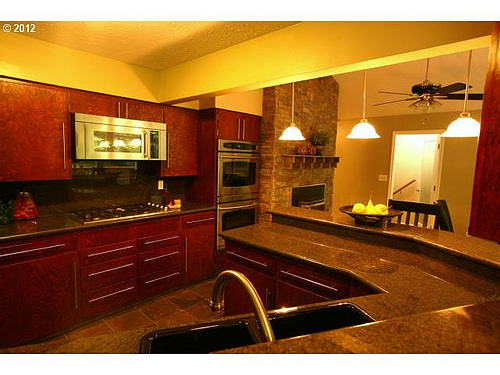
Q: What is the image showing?
A: It is showing a kitchen.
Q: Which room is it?
A: It is a kitchen.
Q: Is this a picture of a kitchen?
A: Yes, it is showing a kitchen.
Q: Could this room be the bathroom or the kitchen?
A: It is the kitchen.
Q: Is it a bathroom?
A: No, it is a kitchen.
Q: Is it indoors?
A: Yes, it is indoors.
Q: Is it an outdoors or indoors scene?
A: It is indoors.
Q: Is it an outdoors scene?
A: No, it is indoors.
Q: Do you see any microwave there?
A: Yes, there is a microwave.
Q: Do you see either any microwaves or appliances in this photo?
A: Yes, there is a microwave.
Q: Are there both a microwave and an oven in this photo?
A: Yes, there are both a microwave and an oven.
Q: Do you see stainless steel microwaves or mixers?
A: Yes, there is a stainless steel microwave.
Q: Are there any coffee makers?
A: No, there are no coffee makers.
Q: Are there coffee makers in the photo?
A: No, there are no coffee makers.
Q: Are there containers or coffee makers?
A: No, there are no coffee makers or containers.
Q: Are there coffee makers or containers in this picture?
A: No, there are no coffee makers or containers.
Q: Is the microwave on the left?
A: Yes, the microwave is on the left of the image.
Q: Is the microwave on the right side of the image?
A: No, the microwave is on the left of the image.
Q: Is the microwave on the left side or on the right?
A: The microwave is on the left of the image.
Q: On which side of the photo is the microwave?
A: The microwave is on the left of the image.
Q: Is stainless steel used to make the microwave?
A: Yes, the microwave is made of stainless steel.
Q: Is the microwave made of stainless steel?
A: Yes, the microwave is made of stainless steel.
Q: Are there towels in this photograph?
A: No, there are no towels.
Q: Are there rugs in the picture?
A: No, there are no rugs.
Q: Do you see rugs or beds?
A: No, there are no rugs or beds.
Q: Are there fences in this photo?
A: No, there are no fences.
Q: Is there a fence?
A: No, there are no fences.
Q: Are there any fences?
A: No, there are no fences.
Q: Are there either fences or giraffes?
A: No, there are no fences or giraffes.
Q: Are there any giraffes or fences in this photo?
A: No, there are no fences or giraffes.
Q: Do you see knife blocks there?
A: No, there are no knife blocks.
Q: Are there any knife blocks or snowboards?
A: No, there are no knife blocks or snowboards.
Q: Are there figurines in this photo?
A: No, there are no figurines.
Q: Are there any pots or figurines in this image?
A: No, there are no figurines or pots.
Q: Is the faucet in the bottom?
A: Yes, the faucet is in the bottom of the image.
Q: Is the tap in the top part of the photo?
A: No, the tap is in the bottom of the image.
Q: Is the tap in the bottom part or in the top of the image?
A: The tap is in the bottom of the image.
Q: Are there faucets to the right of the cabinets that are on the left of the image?
A: Yes, there is a faucet to the right of the cabinets.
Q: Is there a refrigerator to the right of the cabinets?
A: No, there is a faucet to the right of the cabinets.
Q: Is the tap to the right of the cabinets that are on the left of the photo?
A: Yes, the tap is to the right of the cabinets.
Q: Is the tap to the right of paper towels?
A: No, the tap is to the right of the cabinets.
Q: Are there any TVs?
A: No, there are no tvs.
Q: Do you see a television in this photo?
A: No, there are no televisions.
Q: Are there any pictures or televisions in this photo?
A: No, there are no televisions or pictures.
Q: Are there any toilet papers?
A: No, there are no toilet papers.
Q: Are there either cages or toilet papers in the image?
A: No, there are no toilet papers or cages.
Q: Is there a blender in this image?
A: No, there are no blenders.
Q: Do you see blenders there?
A: No, there are no blenders.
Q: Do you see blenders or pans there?
A: No, there are no blenders or pans.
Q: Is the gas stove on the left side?
A: Yes, the gas stove is on the left of the image.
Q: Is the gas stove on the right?
A: No, the gas stove is on the left of the image.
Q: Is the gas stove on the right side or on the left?
A: The gas stove is on the left of the image.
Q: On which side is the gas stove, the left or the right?
A: The gas stove is on the left of the image.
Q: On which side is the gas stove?
A: The gas stove is on the left of the image.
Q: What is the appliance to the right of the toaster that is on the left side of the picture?
A: The appliance is a gas stove.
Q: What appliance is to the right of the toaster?
A: The appliance is a gas stove.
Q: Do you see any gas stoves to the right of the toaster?
A: Yes, there is a gas stove to the right of the toaster.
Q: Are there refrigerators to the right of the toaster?
A: No, there is a gas stove to the right of the toaster.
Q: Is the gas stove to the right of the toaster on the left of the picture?
A: Yes, the gas stove is to the right of the toaster.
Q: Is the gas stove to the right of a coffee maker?
A: No, the gas stove is to the right of the toaster.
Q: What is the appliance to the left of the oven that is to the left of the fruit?
A: The appliance is a gas stove.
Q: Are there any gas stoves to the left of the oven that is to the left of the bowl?
A: Yes, there is a gas stove to the left of the oven.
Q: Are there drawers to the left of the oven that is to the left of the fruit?
A: No, there is a gas stove to the left of the oven.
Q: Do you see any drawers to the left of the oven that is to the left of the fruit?
A: No, there is a gas stove to the left of the oven.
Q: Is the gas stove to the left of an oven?
A: Yes, the gas stove is to the left of an oven.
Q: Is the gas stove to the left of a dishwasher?
A: No, the gas stove is to the left of an oven.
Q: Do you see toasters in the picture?
A: Yes, there is a toaster.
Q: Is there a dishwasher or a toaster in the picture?
A: Yes, there is a toaster.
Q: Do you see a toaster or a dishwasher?
A: Yes, there is a toaster.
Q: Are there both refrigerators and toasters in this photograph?
A: No, there is a toaster but no refrigerators.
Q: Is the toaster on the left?
A: Yes, the toaster is on the left of the image.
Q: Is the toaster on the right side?
A: No, the toaster is on the left of the image.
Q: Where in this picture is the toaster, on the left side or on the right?
A: The toaster is on the left of the image.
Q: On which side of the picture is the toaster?
A: The toaster is on the left of the image.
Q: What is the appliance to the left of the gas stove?
A: The appliance is a toaster.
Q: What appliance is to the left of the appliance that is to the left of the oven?
A: The appliance is a toaster.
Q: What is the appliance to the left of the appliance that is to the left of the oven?
A: The appliance is a toaster.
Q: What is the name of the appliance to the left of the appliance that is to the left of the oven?
A: The appliance is a toaster.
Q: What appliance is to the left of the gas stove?
A: The appliance is a toaster.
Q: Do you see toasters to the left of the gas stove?
A: Yes, there is a toaster to the left of the gas stove.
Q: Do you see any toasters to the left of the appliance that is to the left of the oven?
A: Yes, there is a toaster to the left of the gas stove.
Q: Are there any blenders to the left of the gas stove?
A: No, there is a toaster to the left of the gas stove.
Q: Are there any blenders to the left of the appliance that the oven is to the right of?
A: No, there is a toaster to the left of the gas stove.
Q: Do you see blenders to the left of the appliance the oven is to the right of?
A: No, there is a toaster to the left of the gas stove.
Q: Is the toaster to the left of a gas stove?
A: Yes, the toaster is to the left of a gas stove.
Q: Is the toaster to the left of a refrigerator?
A: No, the toaster is to the left of a gas stove.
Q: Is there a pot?
A: No, there are no pots.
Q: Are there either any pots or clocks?
A: No, there are no pots or clocks.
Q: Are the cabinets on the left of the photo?
A: Yes, the cabinets are on the left of the image.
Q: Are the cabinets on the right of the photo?
A: No, the cabinets are on the left of the image.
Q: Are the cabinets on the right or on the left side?
A: The cabinets are on the left of the image.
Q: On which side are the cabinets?
A: The cabinets are on the left of the image.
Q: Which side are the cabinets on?
A: The cabinets are on the left of the image.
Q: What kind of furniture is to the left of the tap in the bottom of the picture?
A: The pieces of furniture are cabinets.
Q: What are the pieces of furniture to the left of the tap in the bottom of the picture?
A: The pieces of furniture are cabinets.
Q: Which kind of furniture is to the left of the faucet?
A: The pieces of furniture are cabinets.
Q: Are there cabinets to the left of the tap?
A: Yes, there are cabinets to the left of the tap.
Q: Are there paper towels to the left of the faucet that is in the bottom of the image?
A: No, there are cabinets to the left of the tap.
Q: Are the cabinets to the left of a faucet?
A: Yes, the cabinets are to the left of a faucet.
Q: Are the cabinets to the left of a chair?
A: No, the cabinets are to the left of a faucet.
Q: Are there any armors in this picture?
A: No, there are no armors.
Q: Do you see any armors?
A: No, there are no armors.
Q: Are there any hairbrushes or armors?
A: No, there are no armors or hairbrushes.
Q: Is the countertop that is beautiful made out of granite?
A: Yes, the counter top is made of granite.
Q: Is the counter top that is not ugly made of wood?
A: No, the counter top is made of granite.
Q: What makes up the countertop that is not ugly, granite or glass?
A: The counter top is made of granite.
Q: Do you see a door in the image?
A: Yes, there is a door.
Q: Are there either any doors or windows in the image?
A: Yes, there is a door.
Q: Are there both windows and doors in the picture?
A: No, there is a door but no windows.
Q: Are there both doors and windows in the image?
A: No, there is a door but no windows.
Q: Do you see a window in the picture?
A: No, there are no windows.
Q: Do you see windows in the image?
A: No, there are no windows.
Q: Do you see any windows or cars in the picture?
A: No, there are no windows or cars.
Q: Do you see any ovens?
A: Yes, there is an oven.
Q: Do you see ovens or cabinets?
A: Yes, there is an oven.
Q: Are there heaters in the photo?
A: No, there are no heaters.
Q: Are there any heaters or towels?
A: No, there are no heaters or towels.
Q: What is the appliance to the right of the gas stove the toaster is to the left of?
A: The appliance is an oven.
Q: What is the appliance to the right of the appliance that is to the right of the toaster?
A: The appliance is an oven.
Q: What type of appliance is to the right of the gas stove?
A: The appliance is an oven.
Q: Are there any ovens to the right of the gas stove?
A: Yes, there is an oven to the right of the gas stove.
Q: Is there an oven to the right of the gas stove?
A: Yes, there is an oven to the right of the gas stove.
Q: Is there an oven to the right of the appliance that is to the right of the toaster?
A: Yes, there is an oven to the right of the gas stove.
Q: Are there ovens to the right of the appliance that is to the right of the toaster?
A: Yes, there is an oven to the right of the gas stove.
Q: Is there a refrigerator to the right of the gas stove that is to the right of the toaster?
A: No, there is an oven to the right of the gas stove.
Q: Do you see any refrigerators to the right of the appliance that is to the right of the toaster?
A: No, there is an oven to the right of the gas stove.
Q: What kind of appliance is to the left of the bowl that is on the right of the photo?
A: The appliance is an oven.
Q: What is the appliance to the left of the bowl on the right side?
A: The appliance is an oven.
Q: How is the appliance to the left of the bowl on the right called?
A: The appliance is an oven.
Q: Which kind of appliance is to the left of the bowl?
A: The appliance is an oven.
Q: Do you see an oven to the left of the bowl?
A: Yes, there is an oven to the left of the bowl.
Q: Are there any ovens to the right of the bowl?
A: No, the oven is to the left of the bowl.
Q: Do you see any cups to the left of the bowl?
A: No, there is an oven to the left of the bowl.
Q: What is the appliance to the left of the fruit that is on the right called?
A: The appliance is an oven.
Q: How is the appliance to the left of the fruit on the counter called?
A: The appliance is an oven.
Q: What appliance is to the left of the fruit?
A: The appliance is an oven.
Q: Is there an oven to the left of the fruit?
A: Yes, there is an oven to the left of the fruit.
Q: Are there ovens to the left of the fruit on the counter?
A: Yes, there is an oven to the left of the fruit.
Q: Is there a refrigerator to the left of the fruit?
A: No, there is an oven to the left of the fruit.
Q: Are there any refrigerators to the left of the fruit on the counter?
A: No, there is an oven to the left of the fruit.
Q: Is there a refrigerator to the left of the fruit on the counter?
A: No, there is an oven to the left of the fruit.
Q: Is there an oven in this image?
A: Yes, there is an oven.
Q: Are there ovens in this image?
A: Yes, there is an oven.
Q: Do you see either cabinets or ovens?
A: Yes, there is an oven.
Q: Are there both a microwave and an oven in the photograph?
A: Yes, there are both an oven and a microwave.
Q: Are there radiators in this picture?
A: No, there are no radiators.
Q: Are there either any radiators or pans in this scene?
A: No, there are no radiators or pans.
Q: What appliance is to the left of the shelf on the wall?
A: The appliance is an oven.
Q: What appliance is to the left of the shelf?
A: The appliance is an oven.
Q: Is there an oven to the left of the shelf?
A: Yes, there is an oven to the left of the shelf.